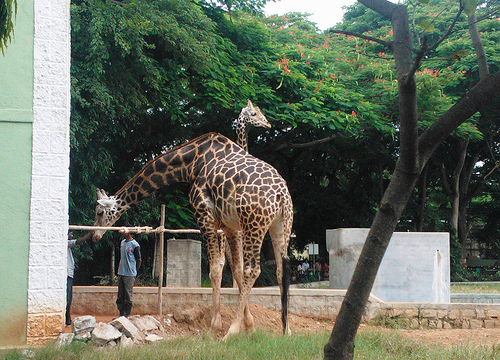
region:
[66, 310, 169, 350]
Large stones sitting on the ground.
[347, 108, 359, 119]
Orange flowers in the trees.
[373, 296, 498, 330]
Wall made of bricks and stones.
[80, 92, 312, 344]
Two giraffes standing outside.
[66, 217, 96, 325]
Man reaching out to touch the giraffe.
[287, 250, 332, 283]
People sitting at a picnic table.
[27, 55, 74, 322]
White stone wall.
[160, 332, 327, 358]
Green grass growing on the ground.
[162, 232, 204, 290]
Large pillar made of gray bricks.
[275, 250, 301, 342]
Giraffe tail with long black hair.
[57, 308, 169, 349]
white rocks on the ground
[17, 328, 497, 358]
green grass on the ground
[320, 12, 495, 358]
brown tree trunk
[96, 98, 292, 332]
spotted pattern on the giraffe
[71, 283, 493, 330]
small brick wall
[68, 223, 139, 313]
two men in the cage with the giraffes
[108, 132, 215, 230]
giraffe's long neck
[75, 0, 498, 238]
green leaves on large trees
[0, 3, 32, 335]
green painted wall color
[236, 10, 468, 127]
orange flowers on the trees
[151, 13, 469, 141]
trees with its branches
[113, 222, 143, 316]
a man standing near the giraffe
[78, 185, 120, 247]
giraffe's head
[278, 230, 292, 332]
tail of the giraffe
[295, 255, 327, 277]
many people are standing under the tree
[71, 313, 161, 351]
stones in the zoo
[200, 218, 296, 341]
legs of the giraffe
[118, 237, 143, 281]
a man wearing blue color t-shirt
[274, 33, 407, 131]
some flowers in the tree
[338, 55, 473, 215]
trees with branches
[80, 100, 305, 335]
two giraffes in a pen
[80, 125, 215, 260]
neck of giraffe is down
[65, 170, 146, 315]
man petting a giraffe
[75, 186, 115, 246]
hand on muzzle of giraffe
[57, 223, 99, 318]
man in front of giraffe wears a blue shirt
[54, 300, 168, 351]
stones in a pen of giraffe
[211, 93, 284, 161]
head of giraffe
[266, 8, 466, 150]
red flowers on a tree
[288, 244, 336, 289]
people behind giraffe's pen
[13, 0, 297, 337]
giraffes in front a building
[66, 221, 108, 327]
A man pets a giraffe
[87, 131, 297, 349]
A giraffe looks down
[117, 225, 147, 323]
A man wears a blue shirt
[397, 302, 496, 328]
A portion of stone fence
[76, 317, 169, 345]
Stones lay on the ground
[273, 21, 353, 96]
Red flecks amidst the leaves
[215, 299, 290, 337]
Dirt piled up against the fence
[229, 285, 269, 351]
Giraffes legs are crossed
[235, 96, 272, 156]
A giraffe with a long neck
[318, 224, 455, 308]
A large cement block